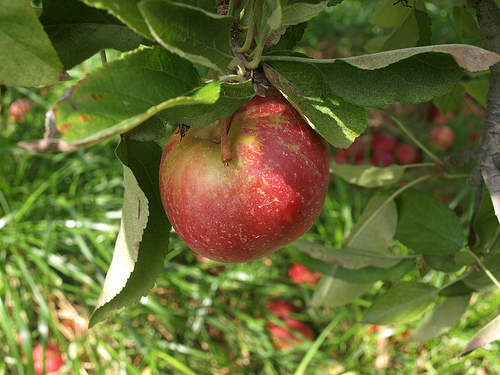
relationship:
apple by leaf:
[160, 91, 330, 265] [33, 43, 252, 152]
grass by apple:
[3, 88, 497, 372] [160, 91, 330, 265]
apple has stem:
[160, 91, 330, 265] [220, 112, 234, 167]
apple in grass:
[160, 91, 330, 265] [3, 88, 497, 372]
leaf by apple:
[33, 43, 252, 152] [160, 91, 330, 265]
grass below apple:
[3, 88, 497, 372] [160, 91, 330, 265]